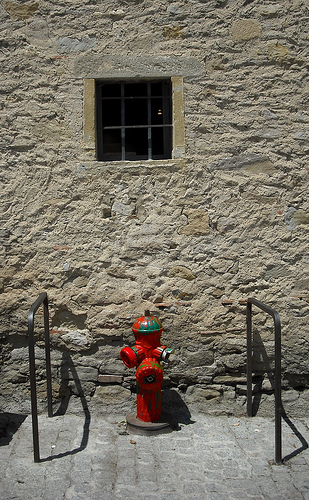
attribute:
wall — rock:
[1, 1, 299, 416]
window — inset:
[77, 71, 219, 186]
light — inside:
[149, 97, 181, 118]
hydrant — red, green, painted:
[89, 321, 226, 428]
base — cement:
[115, 409, 189, 452]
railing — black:
[248, 292, 304, 453]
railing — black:
[12, 292, 75, 461]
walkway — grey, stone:
[34, 409, 298, 495]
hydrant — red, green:
[123, 314, 181, 432]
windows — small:
[91, 65, 183, 207]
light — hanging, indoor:
[145, 99, 173, 120]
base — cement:
[114, 401, 201, 452]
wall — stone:
[5, 28, 276, 280]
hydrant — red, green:
[107, 313, 194, 417]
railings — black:
[222, 293, 299, 408]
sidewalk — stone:
[19, 407, 307, 492]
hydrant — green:
[127, 316, 177, 413]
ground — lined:
[111, 442, 232, 487]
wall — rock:
[67, 175, 259, 272]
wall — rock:
[45, 5, 239, 56]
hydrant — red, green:
[113, 302, 202, 443]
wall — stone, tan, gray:
[19, 35, 304, 297]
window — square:
[63, 64, 193, 167]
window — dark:
[82, 74, 201, 176]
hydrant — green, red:
[128, 318, 190, 428]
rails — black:
[200, 291, 298, 443]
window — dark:
[95, 76, 173, 161]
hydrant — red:
[118, 311, 179, 430]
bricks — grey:
[119, 449, 185, 492]